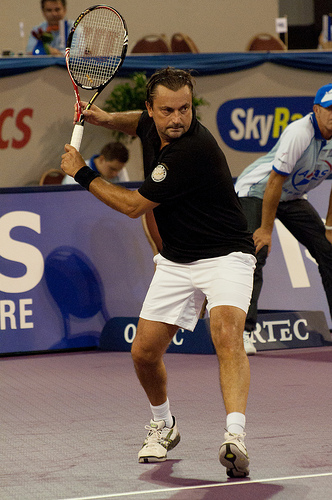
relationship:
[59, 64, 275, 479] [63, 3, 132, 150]
man holding racket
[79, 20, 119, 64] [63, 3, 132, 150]
w on racket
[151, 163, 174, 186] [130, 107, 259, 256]
logo on shirt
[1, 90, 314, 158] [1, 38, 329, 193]
advertisement on wall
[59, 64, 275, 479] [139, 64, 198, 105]
man with hair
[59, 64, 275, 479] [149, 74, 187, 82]
man wearing headband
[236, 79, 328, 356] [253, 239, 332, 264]
man has hands on knees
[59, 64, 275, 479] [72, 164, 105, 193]
man has on wristband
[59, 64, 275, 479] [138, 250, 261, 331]
man wearing shorts